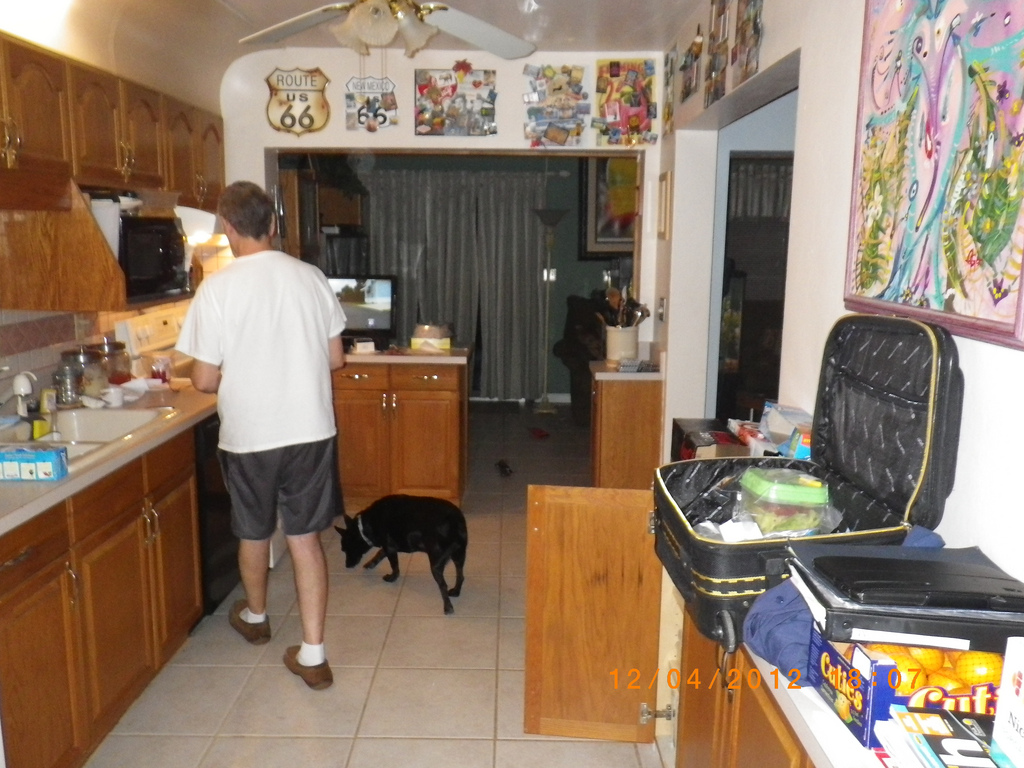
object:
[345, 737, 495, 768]
tile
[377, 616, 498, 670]
tile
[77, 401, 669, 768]
floor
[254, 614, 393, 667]
tile